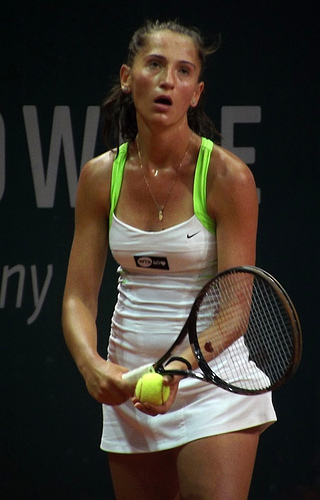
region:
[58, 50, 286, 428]
One woman is playing tennis.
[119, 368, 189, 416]
Ball is yellow color.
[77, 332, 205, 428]
Woman is holding the tennis racket in hand.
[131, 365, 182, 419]
woman is holding ball in left hand.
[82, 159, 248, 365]
Woman is in white and green dress.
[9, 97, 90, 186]
Letters are white color.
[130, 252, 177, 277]
Logo is black color.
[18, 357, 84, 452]
Barrier is black color.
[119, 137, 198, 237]
Woman is wearing chain.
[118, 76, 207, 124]
Woman is wearing earrings.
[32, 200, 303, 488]
picture taken outdoors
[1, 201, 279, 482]
picture taken during the day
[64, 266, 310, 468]
a woman playing tennis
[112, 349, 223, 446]
she is holding a yellow ball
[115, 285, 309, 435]
her right hand holds a tennis racket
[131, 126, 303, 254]
the woman is sweating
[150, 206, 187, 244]
the woman wears a necklace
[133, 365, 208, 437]
the woman holds the ball in her left hand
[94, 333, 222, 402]
the woman holds the racket in her right hand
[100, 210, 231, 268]
her tennis outfit is white and green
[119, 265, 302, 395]
Tennis racket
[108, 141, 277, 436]
White womens unpleated tennis dress with green straps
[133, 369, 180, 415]
Yellow tennis ball in left hand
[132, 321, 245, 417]
black tattoo or birthmark on left forearm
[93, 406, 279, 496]
Short white tennis skirt exposing bare thighs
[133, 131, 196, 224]
charm on chain necklace on sweaty female throat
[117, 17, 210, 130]
Exhausted, sweaty, younger female with mouth open and hair back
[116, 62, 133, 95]
Multiply pierced left earlobe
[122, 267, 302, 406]
Tennis racket and tennis ball in hands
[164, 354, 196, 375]
Black rubber-type slip-on bracelet on left wrist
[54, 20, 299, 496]
a young lady playing tennis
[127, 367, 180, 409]
a green tennis ball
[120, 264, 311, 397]
white and brown racket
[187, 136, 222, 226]
green strap to the dress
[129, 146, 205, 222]
a gold necklace on neck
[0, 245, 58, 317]
white writting on a wall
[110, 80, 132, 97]
a earring in a ear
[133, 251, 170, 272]
a symbol on a dress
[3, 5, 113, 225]
black and white wall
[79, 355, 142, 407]
the right hand holding racket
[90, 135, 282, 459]
the girl is wearing a dress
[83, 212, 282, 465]
the body of the dress is white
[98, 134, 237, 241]
the dress has green straps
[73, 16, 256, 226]
the girl is very sweaty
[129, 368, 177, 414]
the girl is holding a ball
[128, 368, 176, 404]
the ball is a tennis ball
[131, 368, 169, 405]
the tennis ball is fuzzy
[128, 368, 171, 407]
the tennis ball is yellow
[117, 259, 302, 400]
the girl is holding a racket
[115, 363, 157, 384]
the racket has a white handle